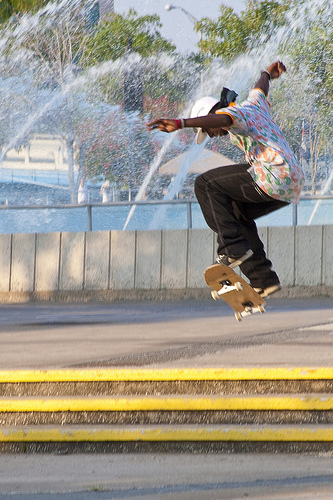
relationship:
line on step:
[2, 367, 332, 385] [0, 365, 330, 398]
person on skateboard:
[143, 62, 298, 296] [202, 261, 268, 325]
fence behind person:
[0, 192, 330, 234] [143, 62, 298, 296]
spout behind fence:
[119, 2, 328, 226] [0, 192, 330, 234]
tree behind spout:
[50, 10, 153, 203] [119, 2, 328, 226]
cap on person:
[186, 96, 219, 145] [143, 62, 298, 296]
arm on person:
[178, 112, 237, 133] [143, 62, 298, 296]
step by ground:
[0, 365, 330, 398] [2, 453, 332, 500]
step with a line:
[0, 365, 330, 398] [2, 367, 332, 385]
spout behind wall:
[119, 2, 328, 226] [0, 224, 330, 304]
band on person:
[177, 117, 187, 131] [143, 62, 298, 296]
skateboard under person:
[202, 261, 268, 325] [143, 62, 298, 296]